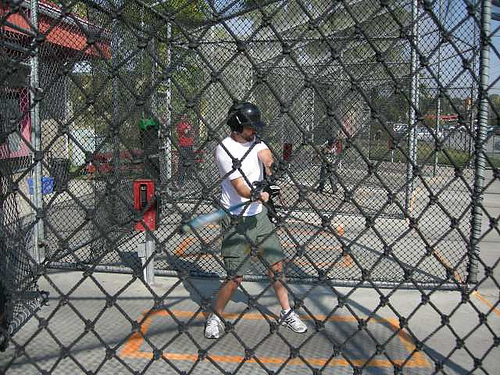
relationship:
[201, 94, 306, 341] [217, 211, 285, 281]
batter wearing shorts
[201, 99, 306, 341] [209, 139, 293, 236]
batter wearing shirt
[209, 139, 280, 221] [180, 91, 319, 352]
shirt on batter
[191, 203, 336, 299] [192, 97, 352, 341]
shorts on man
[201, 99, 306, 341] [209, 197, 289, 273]
batter wearing shorts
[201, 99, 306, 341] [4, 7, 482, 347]
batter using cage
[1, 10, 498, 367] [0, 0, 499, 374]
fence around fence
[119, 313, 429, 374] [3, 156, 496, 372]
batter's box on pavement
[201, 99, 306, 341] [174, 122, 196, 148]
batter wearing shirt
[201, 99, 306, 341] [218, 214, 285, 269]
batter wearing shorts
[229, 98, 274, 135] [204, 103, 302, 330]
helmet on batter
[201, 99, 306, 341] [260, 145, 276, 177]
batter extends arm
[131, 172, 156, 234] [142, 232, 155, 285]
box on a post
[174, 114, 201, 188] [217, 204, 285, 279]
man wearing shorts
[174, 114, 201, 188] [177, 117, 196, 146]
man wearing a shirt